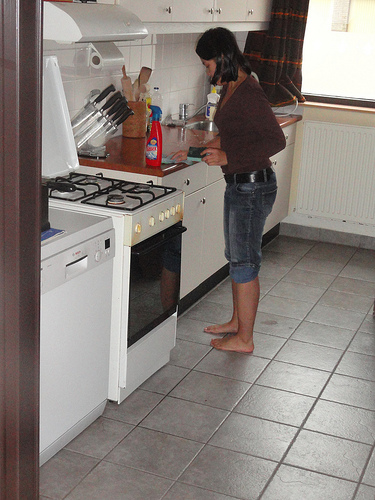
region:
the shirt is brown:
[195, 77, 289, 183]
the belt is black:
[200, 163, 300, 201]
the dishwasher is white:
[39, 225, 143, 440]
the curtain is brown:
[255, 5, 331, 117]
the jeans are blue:
[194, 158, 320, 323]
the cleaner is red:
[137, 94, 192, 200]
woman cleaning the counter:
[139, 31, 319, 322]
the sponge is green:
[178, 140, 240, 190]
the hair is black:
[183, 26, 288, 96]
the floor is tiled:
[151, 325, 311, 485]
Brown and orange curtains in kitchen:
[263, 3, 309, 103]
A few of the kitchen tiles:
[276, 238, 348, 364]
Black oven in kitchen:
[128, 226, 182, 339]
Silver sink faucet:
[179, 99, 193, 123]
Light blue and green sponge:
[187, 144, 208, 161]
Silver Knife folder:
[75, 83, 137, 172]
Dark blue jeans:
[226, 188, 270, 283]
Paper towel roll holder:
[91, 50, 129, 69]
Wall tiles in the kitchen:
[155, 43, 190, 90]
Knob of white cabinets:
[165, 5, 173, 16]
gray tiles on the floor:
[190, 370, 306, 424]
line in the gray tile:
[178, 427, 246, 461]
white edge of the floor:
[50, 419, 99, 443]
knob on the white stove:
[135, 211, 166, 232]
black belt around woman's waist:
[224, 168, 283, 190]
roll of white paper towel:
[77, 40, 139, 81]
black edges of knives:
[84, 82, 144, 137]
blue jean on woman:
[219, 178, 283, 287]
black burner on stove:
[79, 182, 164, 225]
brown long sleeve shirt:
[193, 87, 299, 178]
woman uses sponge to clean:
[125, 118, 201, 196]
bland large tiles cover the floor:
[155, 362, 302, 493]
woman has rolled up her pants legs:
[209, 180, 268, 351]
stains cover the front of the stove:
[122, 200, 185, 245]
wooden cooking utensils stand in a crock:
[119, 63, 151, 139]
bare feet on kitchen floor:
[195, 311, 267, 368]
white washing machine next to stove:
[35, 236, 117, 441]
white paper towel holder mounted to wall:
[82, 44, 121, 76]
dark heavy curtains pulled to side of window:
[260, 15, 299, 98]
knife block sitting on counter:
[77, 84, 126, 155]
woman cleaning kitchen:
[143, 17, 309, 345]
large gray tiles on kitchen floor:
[197, 284, 342, 454]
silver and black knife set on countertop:
[62, 77, 129, 163]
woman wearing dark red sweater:
[191, 22, 284, 183]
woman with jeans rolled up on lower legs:
[202, 49, 290, 360]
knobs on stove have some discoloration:
[68, 172, 197, 241]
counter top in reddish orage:
[78, 118, 209, 181]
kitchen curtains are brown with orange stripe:
[256, 1, 320, 115]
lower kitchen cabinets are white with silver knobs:
[159, 162, 231, 282]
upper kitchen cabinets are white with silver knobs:
[72, 0, 284, 46]